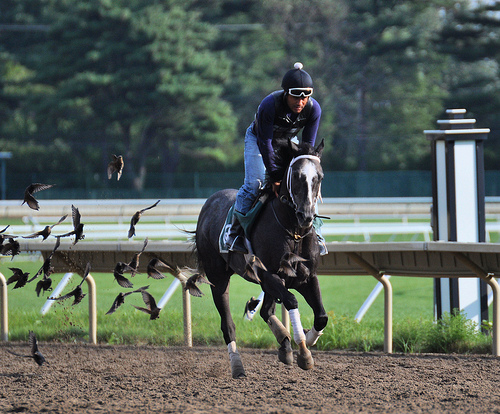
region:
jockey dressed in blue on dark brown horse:
[188, 60, 333, 381]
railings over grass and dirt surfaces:
[5, 185, 495, 405]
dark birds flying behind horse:
[5, 145, 325, 401]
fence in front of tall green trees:
[6, 7, 486, 192]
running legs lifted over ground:
[195, 251, 330, 401]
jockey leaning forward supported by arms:
[215, 60, 323, 252]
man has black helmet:
[269, 59, 312, 104]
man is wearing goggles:
[291, 69, 327, 110]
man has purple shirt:
[258, 106, 320, 149]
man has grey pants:
[234, 147, 257, 204]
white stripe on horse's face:
[288, 139, 345, 213]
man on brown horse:
[189, 208, 341, 318]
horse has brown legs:
[208, 273, 289, 398]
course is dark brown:
[286, 336, 423, 396]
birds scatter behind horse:
[1, 174, 216, 366]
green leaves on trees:
[5, 2, 497, 165]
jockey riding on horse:
[193, 63, 320, 374]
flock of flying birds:
[0, 154, 266, 371]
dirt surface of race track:
[0, 341, 498, 412]